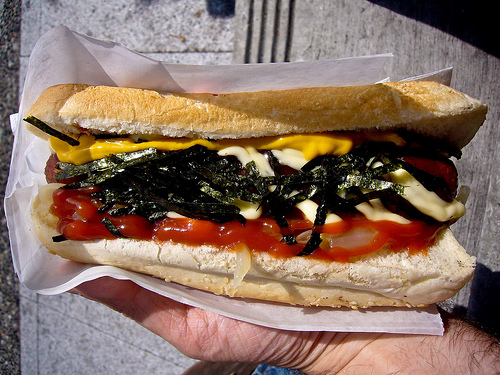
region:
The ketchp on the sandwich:
[55, 191, 431, 264]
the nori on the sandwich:
[39, 143, 413, 256]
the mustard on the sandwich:
[44, 110, 384, 185]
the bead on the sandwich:
[24, 75, 491, 138]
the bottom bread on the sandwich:
[25, 214, 492, 292]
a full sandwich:
[22, 75, 478, 327]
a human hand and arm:
[59, 253, 487, 373]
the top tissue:
[12, 49, 458, 104]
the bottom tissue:
[24, 245, 481, 356]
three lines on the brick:
[229, 40, 306, 85]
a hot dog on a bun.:
[29, 143, 472, 222]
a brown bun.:
[30, 56, 498, 156]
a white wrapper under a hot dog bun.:
[1, 246, 461, 342]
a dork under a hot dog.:
[239, 0, 313, 75]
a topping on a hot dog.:
[46, 142, 421, 260]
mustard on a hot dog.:
[41, 128, 436, 172]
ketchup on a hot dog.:
[40, 194, 454, 248]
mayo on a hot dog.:
[79, 152, 470, 240]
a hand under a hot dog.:
[50, 269, 497, 373]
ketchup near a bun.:
[51, 215, 443, 234]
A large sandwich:
[37, 85, 472, 305]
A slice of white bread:
[32, 83, 477, 140]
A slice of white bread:
[48, 241, 470, 306]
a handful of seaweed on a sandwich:
[50, 154, 392, 222]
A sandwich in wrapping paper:
[14, 25, 489, 327]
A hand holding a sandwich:
[27, 44, 499, 372]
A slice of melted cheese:
[51, 137, 358, 155]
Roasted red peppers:
[58, 208, 425, 248]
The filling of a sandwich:
[46, 140, 471, 244]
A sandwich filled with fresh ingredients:
[44, 89, 483, 302]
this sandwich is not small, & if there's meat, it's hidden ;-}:
[18, 63, 483, 310]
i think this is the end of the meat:
[41, 149, 87, 191]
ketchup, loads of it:
[51, 187, 442, 269]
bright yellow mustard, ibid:
[46, 128, 408, 162]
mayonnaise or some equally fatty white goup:
[85, 140, 470, 237]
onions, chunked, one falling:
[33, 179, 400, 297]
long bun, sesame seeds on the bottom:
[16, 78, 496, 310]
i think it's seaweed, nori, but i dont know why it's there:
[23, 116, 463, 276]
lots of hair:
[370, 312, 498, 372]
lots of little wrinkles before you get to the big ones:
[65, 275, 392, 372]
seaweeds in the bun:
[87, 145, 345, 232]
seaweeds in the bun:
[57, 111, 458, 286]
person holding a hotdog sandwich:
[52, 50, 444, 370]